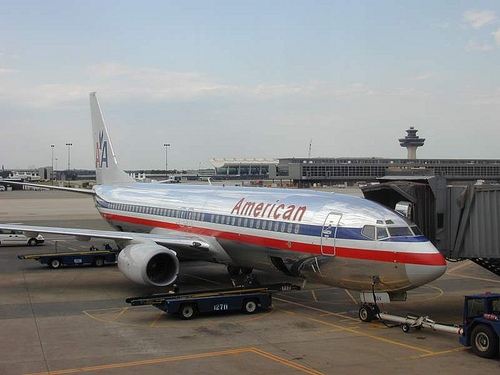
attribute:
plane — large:
[4, 85, 456, 318]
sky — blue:
[3, 0, 499, 177]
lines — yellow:
[17, 303, 433, 373]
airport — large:
[0, 194, 499, 371]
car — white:
[4, 228, 46, 247]